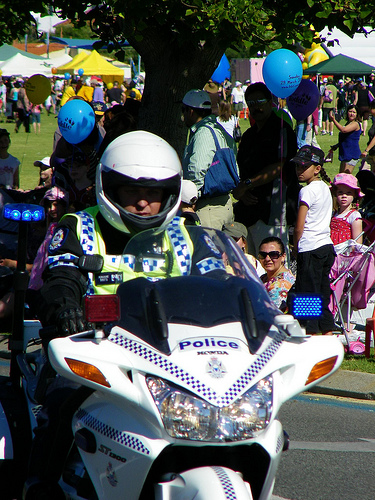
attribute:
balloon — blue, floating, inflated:
[263, 39, 305, 101]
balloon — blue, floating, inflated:
[57, 100, 97, 147]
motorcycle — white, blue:
[3, 241, 350, 499]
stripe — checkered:
[67, 327, 290, 500]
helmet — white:
[90, 129, 191, 235]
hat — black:
[291, 140, 325, 163]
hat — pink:
[327, 166, 363, 196]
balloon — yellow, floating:
[294, 17, 323, 50]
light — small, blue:
[293, 294, 322, 317]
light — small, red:
[84, 294, 124, 323]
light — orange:
[64, 353, 115, 392]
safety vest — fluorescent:
[75, 207, 195, 297]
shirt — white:
[298, 183, 332, 252]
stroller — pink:
[328, 237, 375, 347]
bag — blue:
[183, 126, 237, 200]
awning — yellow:
[49, 47, 128, 78]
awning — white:
[3, 53, 51, 80]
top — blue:
[338, 122, 364, 160]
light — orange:
[303, 352, 337, 389]